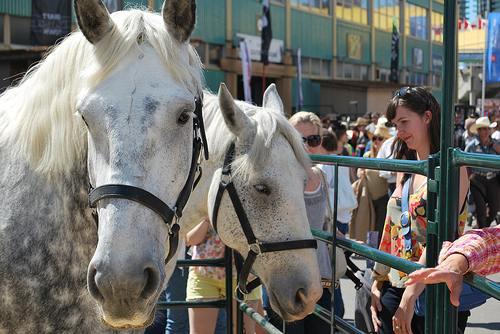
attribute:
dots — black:
[101, 89, 157, 186]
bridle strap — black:
[84, 74, 210, 264]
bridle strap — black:
[208, 143, 317, 301]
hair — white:
[0, 10, 200, 197]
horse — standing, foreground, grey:
[4, 4, 201, 333]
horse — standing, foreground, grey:
[180, 82, 327, 325]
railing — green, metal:
[150, 128, 496, 334]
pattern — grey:
[0, 112, 100, 329]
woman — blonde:
[264, 112, 343, 333]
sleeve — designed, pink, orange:
[440, 223, 499, 279]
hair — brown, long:
[385, 85, 443, 162]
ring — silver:
[167, 213, 182, 236]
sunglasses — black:
[394, 85, 432, 108]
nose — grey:
[82, 223, 167, 330]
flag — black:
[256, 1, 274, 68]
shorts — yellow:
[184, 267, 263, 305]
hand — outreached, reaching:
[405, 247, 468, 306]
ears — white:
[67, 4, 204, 45]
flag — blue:
[483, 9, 498, 85]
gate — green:
[237, 139, 437, 331]